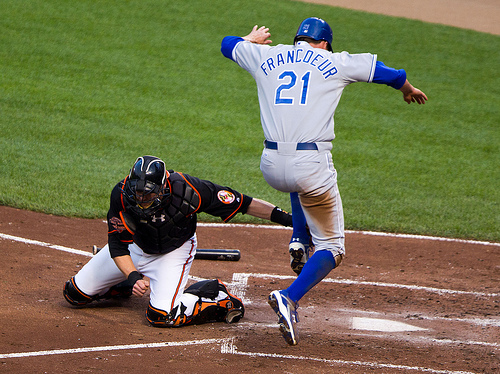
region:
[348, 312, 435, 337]
home plate is white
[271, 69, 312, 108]
number is twenty one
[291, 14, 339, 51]
helmet is blue in color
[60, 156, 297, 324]
catcher is wearing a mask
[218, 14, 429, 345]
man is trying to score a run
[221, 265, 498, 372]
batters box has been used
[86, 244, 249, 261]
bat is laying in the dirt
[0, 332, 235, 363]
chalk line is white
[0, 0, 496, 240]
grass is very green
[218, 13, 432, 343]
man is wearing blue socks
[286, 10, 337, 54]
blue baseball cap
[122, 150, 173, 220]
black baseball cap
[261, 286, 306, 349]
blue and orange sneaker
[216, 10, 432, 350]
baseball player jumping in the air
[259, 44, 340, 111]
name and number on back of jersey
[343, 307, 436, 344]
white baseball diamond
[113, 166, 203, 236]
chest protector on baseball player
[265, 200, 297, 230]
black wristband on wrist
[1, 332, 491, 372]
white lines on baseball field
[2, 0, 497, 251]
green grass on baseball field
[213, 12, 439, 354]
leaping baseball player in gray uniform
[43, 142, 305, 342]
catcher with outstretched arm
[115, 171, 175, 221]
black catcher's safety mask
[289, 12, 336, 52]
dark blue safety helmet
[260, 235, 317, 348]
athletic footwear with cleats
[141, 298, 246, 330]
orange and black safety pads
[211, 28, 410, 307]
gray and blue uniform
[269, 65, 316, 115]
number 21 on player's back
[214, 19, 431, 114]
outstretched arms of baseball player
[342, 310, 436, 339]
home plate embedded in dirt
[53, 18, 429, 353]
two players from opposing teams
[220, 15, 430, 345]
player running with arms lifted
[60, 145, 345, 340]
catcher with extended arm in front of runner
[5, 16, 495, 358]
players on brown dirt with white lines and base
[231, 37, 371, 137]
name curved over number on back of shirt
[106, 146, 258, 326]
black bat behind catcher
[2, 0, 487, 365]
dense green grass behind dirt-covered area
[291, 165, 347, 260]
long patch of dirt in back of thigh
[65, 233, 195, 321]
catcher making fist between legs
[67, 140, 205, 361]
catcher looking down at dirt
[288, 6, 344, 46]
helmet on the batter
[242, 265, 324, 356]
shoe of the player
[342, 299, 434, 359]
white plate on ground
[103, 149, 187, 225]
helmet on the catcher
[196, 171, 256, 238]
black and orange jersey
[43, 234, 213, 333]
pants of the catcher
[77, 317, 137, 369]
white line on ground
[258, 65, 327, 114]
number on back of jersey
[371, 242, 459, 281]
dirt on the ground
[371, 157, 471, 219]
grass on the ground